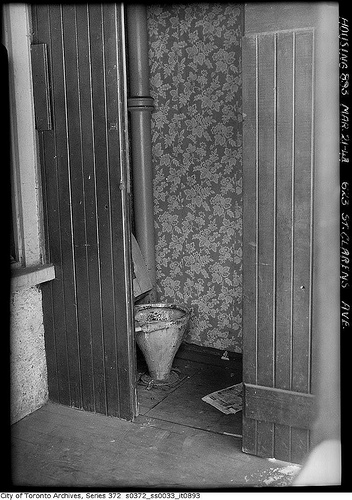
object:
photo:
[2, 4, 350, 489]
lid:
[129, 234, 154, 301]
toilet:
[118, 234, 191, 380]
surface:
[245, 28, 323, 421]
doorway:
[132, 2, 240, 424]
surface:
[60, 414, 187, 482]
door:
[30, 1, 140, 421]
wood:
[277, 61, 331, 456]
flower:
[185, 108, 217, 141]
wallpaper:
[147, 5, 242, 352]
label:
[107, 489, 121, 499]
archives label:
[0, 487, 81, 499]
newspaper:
[201, 381, 244, 416]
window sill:
[11, 264, 57, 285]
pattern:
[208, 261, 232, 286]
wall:
[147, 0, 240, 350]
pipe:
[124, 2, 158, 303]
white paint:
[242, 455, 301, 487]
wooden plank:
[240, 34, 257, 457]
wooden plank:
[255, 32, 275, 458]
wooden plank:
[274, 30, 293, 461]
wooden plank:
[293, 28, 313, 464]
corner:
[7, 229, 37, 266]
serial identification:
[0, 487, 201, 500]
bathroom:
[11, 9, 334, 480]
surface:
[14, 257, 55, 290]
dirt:
[135, 298, 189, 375]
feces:
[142, 311, 168, 325]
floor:
[18, 401, 336, 481]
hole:
[140, 370, 180, 386]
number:
[183, 492, 201, 500]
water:
[136, 168, 157, 298]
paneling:
[248, 0, 336, 458]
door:
[237, 7, 335, 467]